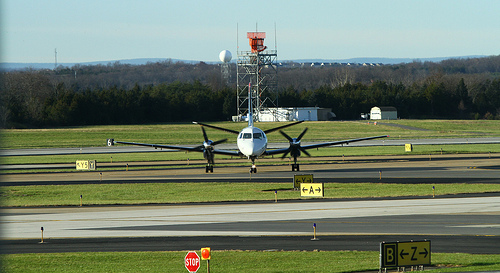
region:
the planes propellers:
[190, 130, 313, 165]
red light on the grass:
[200, 242, 217, 268]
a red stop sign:
[181, 249, 201, 272]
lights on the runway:
[22, 180, 452, 240]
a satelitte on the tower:
[241, 24, 275, 56]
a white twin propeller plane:
[116, 116, 392, 177]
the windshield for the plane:
[241, 131, 263, 141]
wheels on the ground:
[191, 161, 307, 178]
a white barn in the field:
[366, 100, 398, 122]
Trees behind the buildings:
[21, 70, 498, 125]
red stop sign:
[176, 248, 208, 271]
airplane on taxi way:
[101, 117, 399, 174]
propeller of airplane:
[191, 131, 226, 162]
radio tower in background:
[233, 18, 285, 123]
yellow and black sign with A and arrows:
[293, 174, 332, 204]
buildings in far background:
[275, 50, 398, 75]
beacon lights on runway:
[26, 221, 51, 242]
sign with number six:
[97, 127, 118, 148]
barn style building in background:
[362, 101, 403, 121]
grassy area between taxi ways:
[33, 185, 218, 197]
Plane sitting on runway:
[112, 102, 426, 187]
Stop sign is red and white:
[157, 242, 207, 265]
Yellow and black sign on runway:
[293, 178, 330, 202]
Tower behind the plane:
[221, 38, 302, 155]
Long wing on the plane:
[102, 131, 249, 167]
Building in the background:
[245, 97, 332, 127]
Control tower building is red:
[235, 26, 265, 57]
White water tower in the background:
[220, 45, 233, 97]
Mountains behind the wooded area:
[287, 49, 427, 68]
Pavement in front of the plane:
[148, 199, 397, 249]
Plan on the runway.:
[126, 98, 407, 205]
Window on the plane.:
[213, 115, 304, 157]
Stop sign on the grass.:
[173, 245, 223, 269]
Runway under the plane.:
[119, 155, 389, 260]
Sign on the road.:
[283, 153, 378, 239]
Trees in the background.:
[114, 48, 426, 140]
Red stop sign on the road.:
[174, 242, 231, 270]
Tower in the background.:
[211, 22, 273, 82]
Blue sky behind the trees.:
[139, 12, 371, 115]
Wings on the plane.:
[128, 107, 475, 218]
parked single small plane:
[62, 63, 404, 170]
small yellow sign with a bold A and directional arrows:
[264, 153, 369, 231]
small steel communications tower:
[215, 9, 304, 119]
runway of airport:
[27, 192, 457, 270]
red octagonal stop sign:
[165, 238, 199, 270]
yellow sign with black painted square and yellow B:
[353, 212, 440, 270]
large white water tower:
[197, 41, 236, 84]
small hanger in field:
[353, 92, 410, 126]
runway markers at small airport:
[23, 226, 51, 253]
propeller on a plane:
[166, 109, 224, 169]